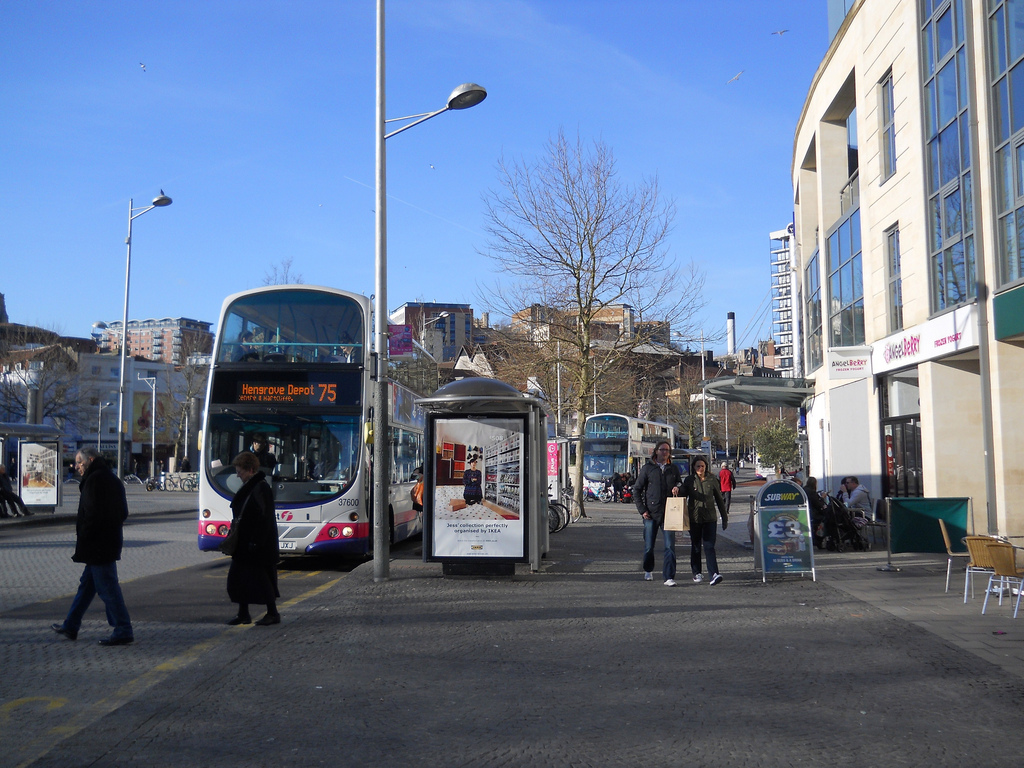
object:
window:
[876, 64, 898, 180]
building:
[785, 0, 1021, 562]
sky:
[0, 0, 862, 362]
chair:
[936, 518, 977, 597]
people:
[671, 457, 729, 586]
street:
[0, 461, 1021, 767]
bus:
[198, 282, 423, 566]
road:
[0, 476, 373, 767]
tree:
[476, 118, 711, 515]